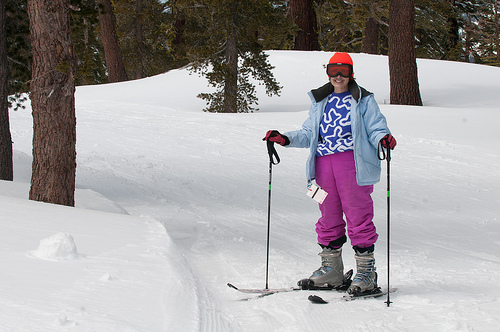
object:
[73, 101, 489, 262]
slope pass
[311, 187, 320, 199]
zipper pull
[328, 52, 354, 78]
cap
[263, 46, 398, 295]
girl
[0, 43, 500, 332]
snow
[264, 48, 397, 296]
skiier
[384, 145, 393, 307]
pole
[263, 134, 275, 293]
poles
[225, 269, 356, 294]
ski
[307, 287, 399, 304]
ski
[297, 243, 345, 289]
boot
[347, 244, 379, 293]
boot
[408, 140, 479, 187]
tracks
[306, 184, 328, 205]
tag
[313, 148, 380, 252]
pants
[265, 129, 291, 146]
glove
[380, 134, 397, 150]
glove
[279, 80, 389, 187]
jacket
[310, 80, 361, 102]
collar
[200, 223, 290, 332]
track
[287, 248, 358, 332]
track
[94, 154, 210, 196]
track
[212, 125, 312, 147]
track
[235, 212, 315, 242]
track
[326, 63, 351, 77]
goggles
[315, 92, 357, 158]
shirt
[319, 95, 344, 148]
lines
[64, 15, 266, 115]
woods